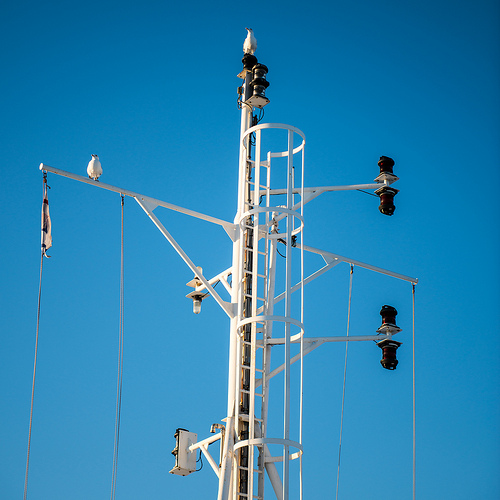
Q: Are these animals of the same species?
A: Yes, all the animals are birds.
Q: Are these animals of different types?
A: No, all the animals are birds.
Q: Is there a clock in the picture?
A: No, there are no clocks.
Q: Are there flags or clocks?
A: No, there are no clocks or flags.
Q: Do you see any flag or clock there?
A: No, there are no clocks or flags.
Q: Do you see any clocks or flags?
A: No, there are no clocks or flags.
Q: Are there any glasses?
A: No, there are no glasses.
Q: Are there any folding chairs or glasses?
A: No, there are no glasses or folding chairs.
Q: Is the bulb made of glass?
A: Yes, the bulb is made of glass.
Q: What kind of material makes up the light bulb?
A: The light bulb is made of glass.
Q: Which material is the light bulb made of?
A: The light bulb is made of glass.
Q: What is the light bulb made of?
A: The light bulb is made of glass.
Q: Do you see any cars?
A: No, there are no cars.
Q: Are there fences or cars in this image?
A: No, there are no cars or fences.